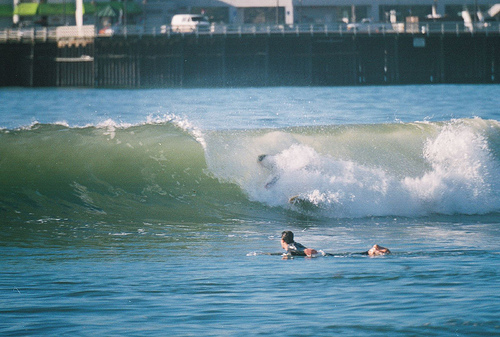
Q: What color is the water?
A: Blue.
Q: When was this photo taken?
A: Outside, during the daytime.